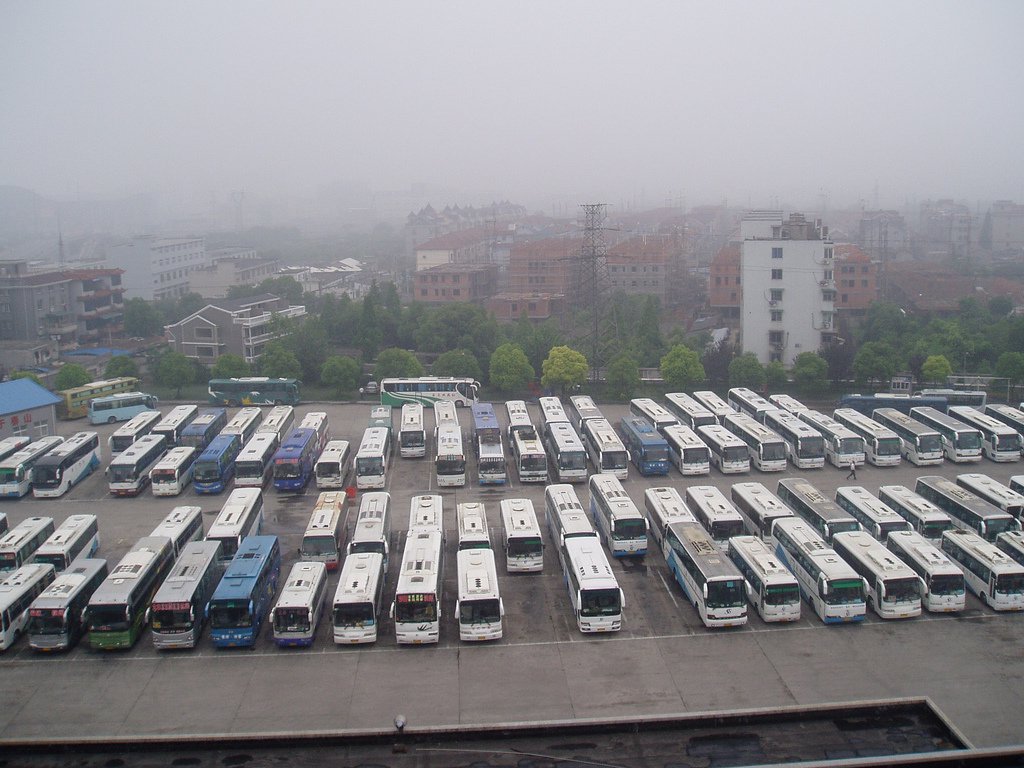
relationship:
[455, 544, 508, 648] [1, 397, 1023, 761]
bus parked in parking lot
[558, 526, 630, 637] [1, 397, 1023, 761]
bus parked in parking lot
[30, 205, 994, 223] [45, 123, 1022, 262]
grey overcast sky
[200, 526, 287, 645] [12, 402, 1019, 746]
bus parked in lot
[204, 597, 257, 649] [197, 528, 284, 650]
front belonging to bus